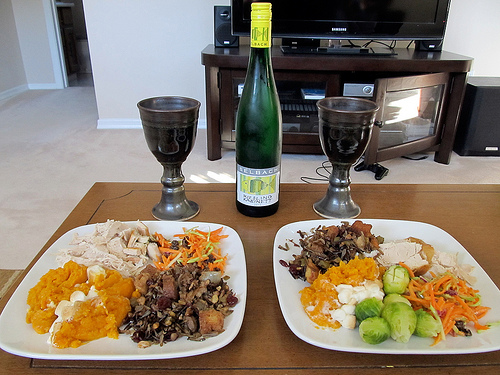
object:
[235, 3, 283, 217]
bottle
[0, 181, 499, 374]
table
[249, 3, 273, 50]
cap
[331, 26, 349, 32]
logo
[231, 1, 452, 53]
television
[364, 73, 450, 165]
door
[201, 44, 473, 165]
cabinet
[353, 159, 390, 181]
controller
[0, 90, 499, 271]
ground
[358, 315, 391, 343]
cabbage balls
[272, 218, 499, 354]
plate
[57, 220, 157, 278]
meat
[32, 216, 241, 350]
food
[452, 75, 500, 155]
speaker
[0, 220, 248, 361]
plates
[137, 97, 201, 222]
wine glass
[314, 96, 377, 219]
goblet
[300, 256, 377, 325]
sweet potatoes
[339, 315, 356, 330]
marshmallows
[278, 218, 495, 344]
food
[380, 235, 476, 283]
chicken breast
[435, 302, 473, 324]
carrots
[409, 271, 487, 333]
salad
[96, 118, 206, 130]
baseboard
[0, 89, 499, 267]
carpet